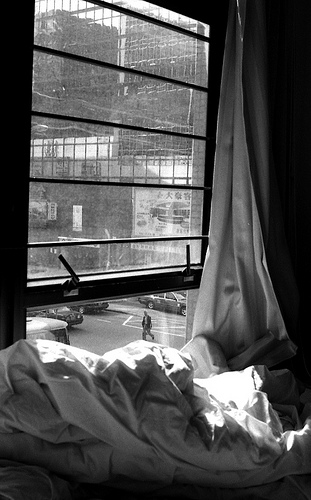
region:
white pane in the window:
[34, 37, 65, 73]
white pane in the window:
[75, 154, 107, 189]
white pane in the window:
[105, 168, 173, 259]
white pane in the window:
[145, 200, 192, 264]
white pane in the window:
[171, 104, 232, 159]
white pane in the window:
[24, 87, 120, 178]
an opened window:
[26, 30, 297, 387]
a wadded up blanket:
[18, 322, 303, 481]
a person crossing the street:
[127, 288, 172, 348]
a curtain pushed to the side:
[182, 22, 294, 384]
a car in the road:
[126, 277, 194, 330]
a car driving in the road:
[35, 292, 100, 342]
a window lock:
[46, 245, 94, 308]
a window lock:
[174, 235, 213, 313]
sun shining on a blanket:
[54, 305, 309, 445]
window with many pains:
[28, 23, 230, 287]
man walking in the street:
[139, 308, 155, 343]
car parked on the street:
[136, 290, 188, 317]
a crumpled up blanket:
[2, 335, 308, 490]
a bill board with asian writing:
[127, 183, 192, 255]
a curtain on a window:
[189, 0, 309, 372]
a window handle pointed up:
[54, 250, 81, 295]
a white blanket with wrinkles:
[0, 336, 301, 498]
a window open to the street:
[16, 0, 213, 348]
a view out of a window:
[26, 1, 211, 367]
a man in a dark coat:
[136, 307, 155, 342]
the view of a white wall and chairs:
[150, 50, 181, 62]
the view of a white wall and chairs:
[173, 465, 179, 479]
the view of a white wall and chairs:
[184, 448, 191, 461]